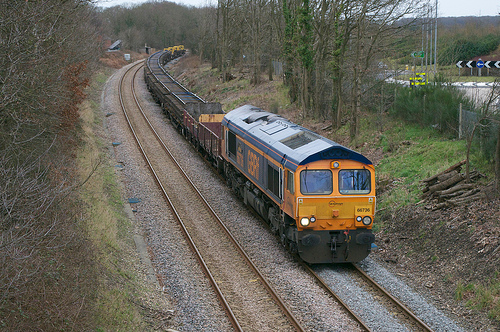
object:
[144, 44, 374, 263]
train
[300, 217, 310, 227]
headlights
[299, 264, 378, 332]
tracks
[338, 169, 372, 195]
windshield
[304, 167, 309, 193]
wiper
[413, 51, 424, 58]
sign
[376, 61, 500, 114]
highway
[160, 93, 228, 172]
cars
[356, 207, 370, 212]
number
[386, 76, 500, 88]
lot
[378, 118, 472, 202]
coutryside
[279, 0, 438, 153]
tree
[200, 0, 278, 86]
trees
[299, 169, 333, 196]
window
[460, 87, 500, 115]
area